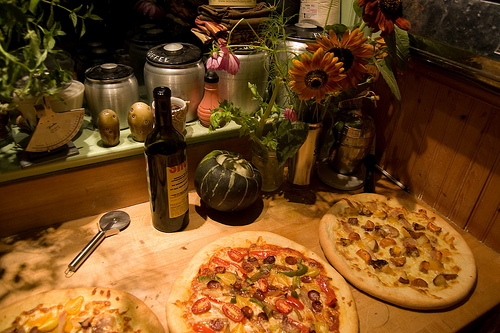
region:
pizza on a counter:
[310, 186, 489, 304]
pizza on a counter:
[157, 238, 362, 330]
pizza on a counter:
[0, 283, 157, 331]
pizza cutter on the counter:
[49, 202, 138, 274]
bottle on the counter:
[144, 72, 199, 234]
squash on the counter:
[199, 145, 259, 223]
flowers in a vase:
[281, 38, 369, 195]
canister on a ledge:
[85, 57, 142, 124]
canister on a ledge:
[145, 36, 202, 101]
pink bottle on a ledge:
[197, 60, 229, 131]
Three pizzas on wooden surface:
[0, 189, 467, 331]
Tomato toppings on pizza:
[193, 248, 333, 331]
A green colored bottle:
[143, 83, 193, 235]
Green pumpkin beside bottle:
[196, 145, 265, 215]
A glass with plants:
[211, 77, 308, 190]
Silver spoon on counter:
[64, 205, 131, 281]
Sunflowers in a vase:
[293, 32, 374, 188]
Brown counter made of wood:
[0, 203, 497, 331]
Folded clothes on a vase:
[195, 3, 277, 47]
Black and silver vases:
[82, 41, 267, 116]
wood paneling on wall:
[365, 58, 499, 255]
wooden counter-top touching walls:
[0, 149, 499, 331]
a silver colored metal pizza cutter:
[68, 208, 130, 273]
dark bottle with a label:
[143, 85, 190, 231]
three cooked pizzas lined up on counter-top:
[1, 161, 497, 331]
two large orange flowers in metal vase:
[287, 26, 373, 196]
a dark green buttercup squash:
[194, 146, 262, 214]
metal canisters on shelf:
[84, 21, 319, 127]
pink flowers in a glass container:
[205, 1, 295, 192]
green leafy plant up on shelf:
[2, 1, 104, 166]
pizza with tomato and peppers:
[166, 231, 360, 332]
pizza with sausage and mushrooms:
[318, 194, 477, 310]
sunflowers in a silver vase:
[287, 27, 379, 188]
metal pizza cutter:
[64, 211, 131, 275]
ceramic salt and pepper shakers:
[96, 102, 153, 145]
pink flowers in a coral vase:
[196, 44, 238, 126]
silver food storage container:
[143, 42, 206, 124]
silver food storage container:
[83, 62, 139, 129]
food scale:
[25, 94, 84, 164]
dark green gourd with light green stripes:
[192, 148, 261, 215]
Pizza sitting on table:
[318, 191, 477, 311]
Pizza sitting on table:
[166, 230, 359, 332]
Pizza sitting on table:
[0, 285, 166, 332]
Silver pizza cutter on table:
[66, 210, 131, 276]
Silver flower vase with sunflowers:
[281, 26, 376, 194]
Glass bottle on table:
[143, 86, 193, 234]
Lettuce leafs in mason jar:
[205, 78, 309, 194]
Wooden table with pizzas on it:
[1, 144, 498, 331]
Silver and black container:
[82, 62, 139, 134]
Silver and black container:
[143, 40, 208, 124]